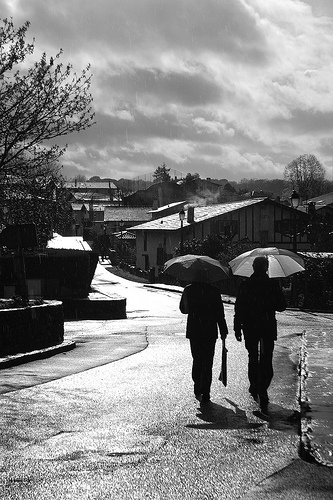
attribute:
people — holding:
[177, 256, 288, 406]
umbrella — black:
[161, 254, 233, 283]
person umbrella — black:
[230, 247, 312, 398]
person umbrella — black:
[157, 249, 232, 400]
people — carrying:
[168, 262, 330, 408]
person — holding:
[179, 283, 228, 408]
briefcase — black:
[209, 332, 229, 384]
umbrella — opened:
[226, 243, 307, 279]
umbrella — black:
[225, 221, 311, 268]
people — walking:
[162, 250, 237, 420]